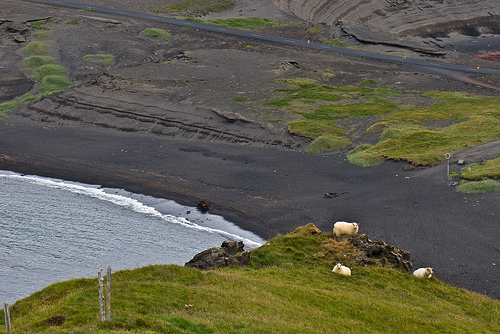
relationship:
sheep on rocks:
[332, 218, 358, 238] [272, 227, 412, 272]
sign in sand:
[444, 149, 454, 160] [3, 0, 496, 299]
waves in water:
[92, 184, 160, 226] [8, 184, 160, 263]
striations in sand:
[29, 87, 302, 152] [3, 0, 496, 299]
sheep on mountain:
[332, 218, 358, 238] [2, 217, 496, 330]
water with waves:
[0, 170, 263, 307] [1, 171, 261, 249]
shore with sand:
[1, 155, 268, 256] [3, 0, 496, 299]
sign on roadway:
[471, 62, 484, 75] [272, 28, 357, 63]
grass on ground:
[383, 106, 473, 151] [226, 110, 308, 219]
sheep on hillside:
[332, 218, 358, 238] [2, 222, 498, 332]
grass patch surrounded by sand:
[276, 76, 499, 168] [3, 0, 496, 299]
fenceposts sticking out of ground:
[93, 267, 108, 324] [12, 213, 495, 332]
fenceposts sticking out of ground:
[102, 260, 114, 324] [12, 213, 495, 332]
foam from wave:
[42, 174, 160, 217] [2, 170, 268, 253]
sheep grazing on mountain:
[332, 218, 358, 238] [2, 217, 496, 330]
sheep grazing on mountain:
[413, 266, 434, 278] [2, 217, 496, 330]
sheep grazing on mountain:
[332, 263, 352, 277] [2, 217, 496, 330]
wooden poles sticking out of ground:
[88, 264, 115, 326] [130, 277, 298, 324]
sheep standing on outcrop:
[332, 218, 358, 238] [348, 232, 416, 273]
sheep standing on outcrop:
[413, 266, 435, 278] [348, 232, 416, 273]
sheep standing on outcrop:
[331, 261, 352, 274] [348, 232, 416, 273]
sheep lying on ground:
[332, 263, 352, 277] [2, 229, 498, 332]